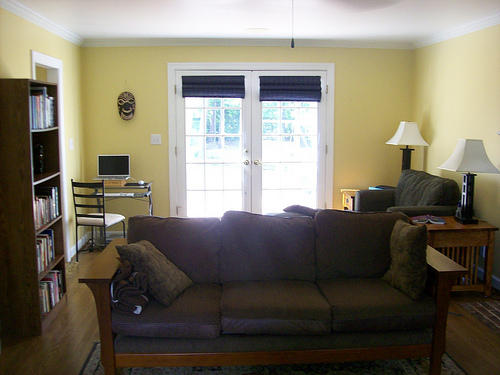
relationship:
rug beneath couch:
[79, 341, 466, 375] [76, 215, 470, 373]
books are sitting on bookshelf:
[30, 89, 67, 319] [0, 78, 67, 339]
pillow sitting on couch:
[383, 220, 430, 301] [76, 215, 470, 373]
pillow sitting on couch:
[114, 238, 195, 306] [76, 215, 470, 373]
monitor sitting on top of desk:
[97, 153, 132, 179] [91, 180, 154, 236]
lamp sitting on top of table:
[437, 136, 499, 227] [408, 213, 498, 299]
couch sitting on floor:
[76, 215, 470, 373] [2, 235, 500, 373]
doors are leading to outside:
[174, 66, 329, 221] [188, 100, 311, 204]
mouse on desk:
[134, 177, 145, 186] [91, 180, 154, 236]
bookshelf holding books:
[3, 79, 72, 336] [30, 89, 67, 319]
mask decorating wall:
[117, 88, 136, 123] [83, 46, 427, 232]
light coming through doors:
[188, 98, 314, 199] [174, 66, 329, 221]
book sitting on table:
[412, 215, 447, 227] [408, 213, 498, 299]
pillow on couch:
[383, 220, 430, 301] [76, 209, 471, 373]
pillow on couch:
[114, 238, 195, 306] [76, 209, 471, 373]